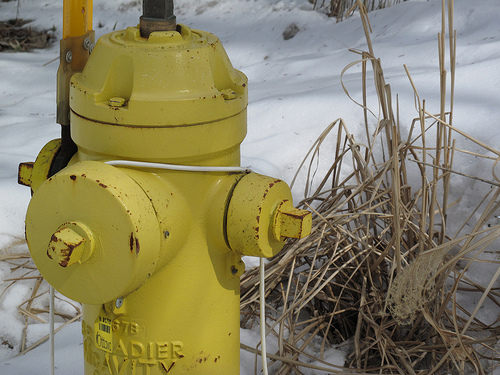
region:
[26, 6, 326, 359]
yellow fire hydrant in snow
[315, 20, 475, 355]
bent and curled dead stalks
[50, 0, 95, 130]
yellow pole with screws in panel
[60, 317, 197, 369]
raised lettering on hydrant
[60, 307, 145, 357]
yellow and black sticker over lettering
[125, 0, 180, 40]
silver plug on top of hydrant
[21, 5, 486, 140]
slight slope in back of grass and hydrant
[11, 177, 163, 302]
worn edges on extended hydrant part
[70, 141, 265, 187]
white cord horizontally across hydrant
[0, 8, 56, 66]
pile of debris on snow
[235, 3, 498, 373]
clump of tan coloured dead straw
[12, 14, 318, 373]
rusty yellow fire hydrant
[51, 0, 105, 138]
base of a yellow metal pole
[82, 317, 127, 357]
yellow sticker with a bar code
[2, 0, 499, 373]
white snow covered ground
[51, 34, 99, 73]
two silver metal bolts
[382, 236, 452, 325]
whispy tan dead plant material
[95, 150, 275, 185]
white piece of wire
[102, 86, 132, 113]
yellow metal bolt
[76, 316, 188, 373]
raised lettering on the fire hydrant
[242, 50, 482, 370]
some dry, dead grass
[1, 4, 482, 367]
the ground covered in snow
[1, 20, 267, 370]
a yellow fire hydrant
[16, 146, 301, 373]
some rope on the hydrant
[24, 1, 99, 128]
a handle attached to the hydrant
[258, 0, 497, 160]
a small, snowy hill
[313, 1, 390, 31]
some dry, dead grass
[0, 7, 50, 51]
some dry, dead grass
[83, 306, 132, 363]
a tag on the hydrant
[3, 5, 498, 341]
a snowy landscape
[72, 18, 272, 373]
yellow fire plug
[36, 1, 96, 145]
yellow wrench on fire plug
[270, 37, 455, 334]
dead grass next to fire plug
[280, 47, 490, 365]
dead brown grass in snow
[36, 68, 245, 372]
brown rust on fire plug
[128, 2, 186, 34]
metal top of fire plug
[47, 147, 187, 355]
yellow paint on fire plug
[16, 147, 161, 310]
rusted fire plug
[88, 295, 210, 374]
manufacturer name on fire plug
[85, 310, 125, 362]
yellow sticker on fire plug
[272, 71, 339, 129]
snow on the ground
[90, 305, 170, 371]
words on the hydrant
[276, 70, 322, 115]
white snow on the ground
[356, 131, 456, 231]
sticks next to the hydrant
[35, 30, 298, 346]
yellow fire hydrant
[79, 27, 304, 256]
hydrant next to the snow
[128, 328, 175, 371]
yellow letters on the hydrant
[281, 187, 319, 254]
edge of the hydrant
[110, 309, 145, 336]
numbers on the hydrant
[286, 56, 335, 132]
shadow on the snow